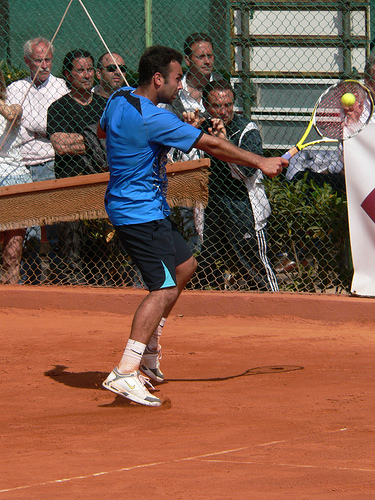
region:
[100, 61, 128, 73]
dark black sunglasses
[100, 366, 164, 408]
a man's tennis shoe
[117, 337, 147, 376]
a man's white sock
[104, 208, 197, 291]
a man's shorts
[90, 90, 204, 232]
a man's short sleeve shirt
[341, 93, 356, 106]
a green tennis ball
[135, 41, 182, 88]
a man's short cut hair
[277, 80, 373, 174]
a large tennis racket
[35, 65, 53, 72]
a gray mustache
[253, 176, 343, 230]
part of a green bush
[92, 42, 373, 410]
A tennis player hitting a backhand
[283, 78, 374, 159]
A tennis racket and ball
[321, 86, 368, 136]
A tennis ball on the strings of a racket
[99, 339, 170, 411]
Feet in tennis shoes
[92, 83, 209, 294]
Blue and black tennis clothes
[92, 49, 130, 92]
A man's head in sunglasses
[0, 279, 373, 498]
A red clay tennis court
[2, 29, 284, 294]
A group of tennis spectators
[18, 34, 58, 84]
An older man with a mustache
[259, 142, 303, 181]
A hand gripping a tennis racket handle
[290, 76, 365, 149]
He is hitting the ball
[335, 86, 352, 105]
the ball is green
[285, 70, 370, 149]
the racket is yellow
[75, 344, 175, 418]
his shoes are white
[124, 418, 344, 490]
the white line is fading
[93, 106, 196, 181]
his shirt is blue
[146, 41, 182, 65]
his hair is black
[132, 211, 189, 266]
his shorts are black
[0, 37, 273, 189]
spectators are watching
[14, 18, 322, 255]
the fence is metal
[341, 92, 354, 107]
the tennis ball in mid air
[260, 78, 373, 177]
the tennis racquet in the man's hand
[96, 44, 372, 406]
the man playing tennis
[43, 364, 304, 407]
the shadow on the ground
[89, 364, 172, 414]
the dirt being kicked up by the man's foot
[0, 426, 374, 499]
the fading white lines on the dirt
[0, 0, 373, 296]
the chain link fence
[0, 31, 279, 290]
the people on the other side of the fence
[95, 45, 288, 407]
the man wearing a short sleeved blue shirt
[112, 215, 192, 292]
the dark shorts on the man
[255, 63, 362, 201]
He is playing tennis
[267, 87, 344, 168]
the racket is yellow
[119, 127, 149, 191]
his shirt is blue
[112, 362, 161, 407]
His shoes are white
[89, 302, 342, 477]
the court is brown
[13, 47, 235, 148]
Spectators behind the fence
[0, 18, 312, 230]
The fence is metal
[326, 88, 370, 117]
The ball is green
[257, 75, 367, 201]
The ball is being hit